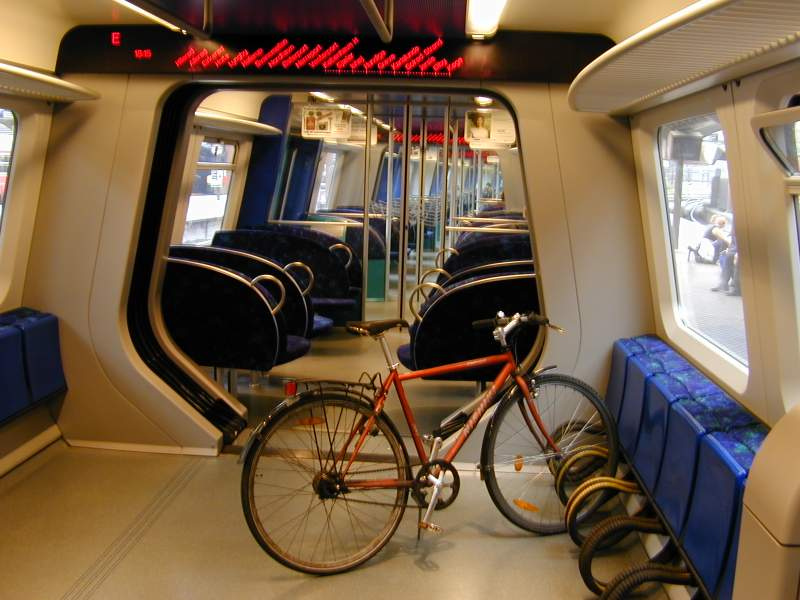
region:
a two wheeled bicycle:
[224, 304, 632, 574]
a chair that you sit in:
[169, 252, 308, 408]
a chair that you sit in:
[395, 264, 541, 390]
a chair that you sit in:
[178, 240, 330, 354]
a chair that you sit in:
[205, 217, 365, 316]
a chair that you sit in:
[387, 251, 542, 323]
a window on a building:
[655, 121, 746, 371]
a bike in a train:
[224, 287, 617, 587]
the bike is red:
[231, 300, 596, 586]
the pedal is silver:
[407, 457, 452, 545]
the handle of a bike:
[481, 308, 531, 358]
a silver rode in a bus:
[349, 87, 379, 340]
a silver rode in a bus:
[400, 97, 416, 333]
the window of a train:
[638, 102, 764, 398]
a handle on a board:
[246, 259, 294, 327]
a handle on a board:
[324, 232, 361, 276]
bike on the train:
[228, 298, 638, 576]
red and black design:
[89, 21, 501, 83]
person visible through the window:
[714, 218, 743, 296]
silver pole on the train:
[355, 90, 383, 333]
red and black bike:
[225, 308, 644, 567]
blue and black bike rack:
[521, 330, 785, 598]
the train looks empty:
[3, 2, 799, 598]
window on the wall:
[641, 107, 758, 367]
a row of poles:
[362, 90, 508, 349]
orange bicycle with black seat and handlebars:
[233, 311, 619, 580]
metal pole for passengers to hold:
[390, 96, 415, 330]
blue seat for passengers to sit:
[162, 245, 319, 379]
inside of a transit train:
[16, 11, 782, 584]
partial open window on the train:
[745, 100, 796, 182]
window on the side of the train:
[651, 110, 750, 368]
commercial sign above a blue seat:
[294, 102, 355, 143]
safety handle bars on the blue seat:
[248, 258, 320, 315]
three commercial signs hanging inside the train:
[293, 103, 515, 152]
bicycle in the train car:
[217, 280, 617, 568]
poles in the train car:
[344, 91, 482, 324]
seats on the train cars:
[166, 185, 536, 377]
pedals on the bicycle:
[402, 418, 455, 535]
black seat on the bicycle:
[351, 310, 409, 345]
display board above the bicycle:
[56, 16, 597, 81]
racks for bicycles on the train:
[506, 335, 758, 592]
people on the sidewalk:
[695, 196, 743, 305]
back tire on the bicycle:
[239, 395, 426, 566]